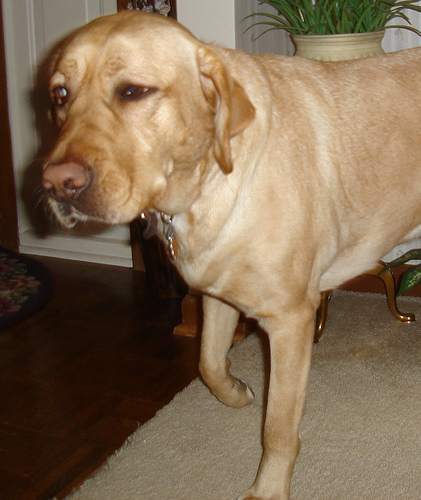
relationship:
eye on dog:
[116, 75, 162, 102] [34, 10, 420, 500]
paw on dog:
[214, 376, 258, 412] [34, 10, 420, 500]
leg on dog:
[250, 313, 310, 491] [34, 10, 420, 500]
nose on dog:
[39, 161, 92, 197] [34, 10, 420, 500]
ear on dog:
[199, 51, 256, 176] [34, 10, 420, 500]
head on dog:
[39, 8, 238, 228] [34, 10, 420, 500]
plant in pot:
[245, 0, 419, 38] [288, 28, 389, 66]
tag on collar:
[164, 227, 185, 260] [142, 175, 218, 241]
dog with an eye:
[34, 10, 420, 500] [116, 75, 162, 102]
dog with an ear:
[34, 10, 420, 500] [199, 51, 256, 176]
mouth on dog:
[67, 186, 170, 240] [34, 10, 420, 500]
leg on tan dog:
[250, 313, 310, 491] [34, 10, 420, 500]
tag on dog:
[164, 227, 185, 260] [34, 10, 420, 500]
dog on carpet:
[34, 10, 420, 500] [60, 290, 420, 499]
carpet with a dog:
[60, 290, 420, 499] [34, 10, 420, 500]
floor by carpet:
[0, 256, 238, 498] [60, 290, 420, 499]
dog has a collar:
[34, 10, 420, 500] [142, 175, 218, 241]